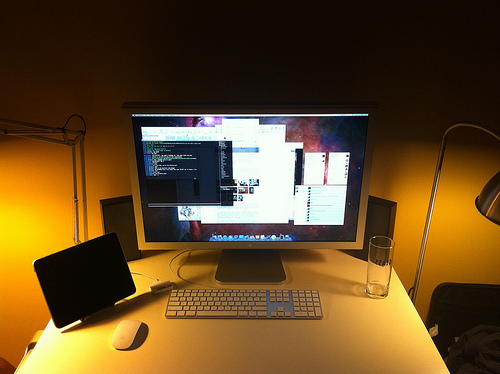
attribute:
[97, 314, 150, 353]
mouse — white, apple, wireless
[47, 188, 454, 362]
desk — white, clean, white table, large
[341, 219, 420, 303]
glass — empty, clear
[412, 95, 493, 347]
floor lamp — silver, stainless steel, tall, on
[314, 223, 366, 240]
clock — off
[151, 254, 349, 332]
keyboard — apple, silver, white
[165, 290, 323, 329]
keys — white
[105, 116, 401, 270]
monitor — apple, on, big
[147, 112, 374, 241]
screen — lit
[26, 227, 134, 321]
tablet — black